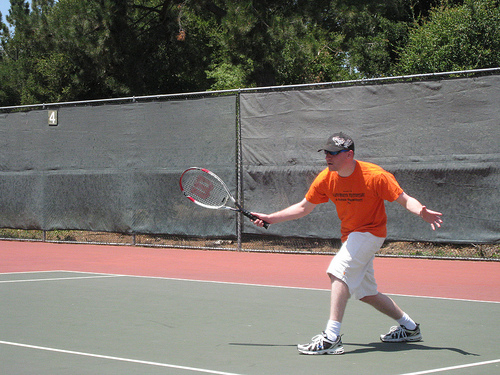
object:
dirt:
[2, 230, 500, 254]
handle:
[239, 209, 271, 230]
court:
[1, 235, 500, 375]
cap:
[317, 132, 355, 152]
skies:
[0, 0, 36, 32]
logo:
[190, 175, 215, 199]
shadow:
[341, 341, 481, 357]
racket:
[179, 166, 271, 230]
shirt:
[305, 159, 405, 243]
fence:
[0, 68, 500, 244]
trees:
[0, 0, 499, 105]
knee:
[329, 266, 342, 284]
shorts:
[325, 232, 386, 301]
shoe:
[296, 330, 344, 355]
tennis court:
[0, 239, 499, 374]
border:
[0, 236, 499, 263]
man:
[249, 131, 443, 356]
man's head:
[325, 131, 356, 170]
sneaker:
[379, 322, 423, 343]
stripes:
[303, 340, 325, 352]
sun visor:
[317, 145, 345, 151]